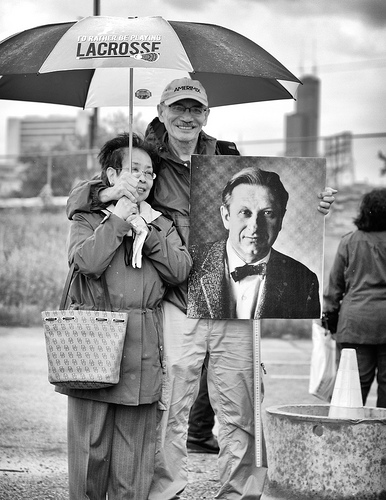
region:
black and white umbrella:
[9, 10, 290, 129]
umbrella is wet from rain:
[23, 15, 284, 125]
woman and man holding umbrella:
[72, 37, 229, 236]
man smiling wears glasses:
[154, 79, 238, 158]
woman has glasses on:
[78, 132, 175, 222]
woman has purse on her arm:
[51, 130, 210, 390]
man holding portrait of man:
[142, 91, 307, 325]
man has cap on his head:
[141, 81, 259, 160]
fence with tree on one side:
[3, 142, 92, 216]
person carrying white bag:
[299, 195, 384, 382]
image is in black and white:
[28, 285, 288, 429]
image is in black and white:
[50, 357, 293, 478]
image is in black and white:
[79, 400, 310, 497]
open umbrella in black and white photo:
[6, 18, 298, 114]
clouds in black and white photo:
[284, 12, 374, 62]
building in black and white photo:
[11, 114, 84, 166]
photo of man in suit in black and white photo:
[191, 136, 332, 338]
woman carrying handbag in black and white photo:
[34, 303, 133, 402]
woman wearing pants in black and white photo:
[62, 393, 156, 495]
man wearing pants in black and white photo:
[163, 283, 267, 482]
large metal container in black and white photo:
[261, 387, 375, 497]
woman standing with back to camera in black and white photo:
[337, 181, 383, 341]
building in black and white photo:
[301, 54, 380, 193]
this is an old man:
[147, 88, 207, 143]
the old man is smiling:
[173, 123, 196, 130]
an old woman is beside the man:
[93, 147, 151, 250]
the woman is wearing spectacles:
[135, 169, 157, 178]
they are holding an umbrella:
[115, 154, 137, 219]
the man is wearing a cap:
[166, 79, 199, 100]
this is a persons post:
[195, 161, 323, 305]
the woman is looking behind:
[339, 238, 379, 332]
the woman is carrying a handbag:
[40, 289, 136, 387]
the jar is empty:
[264, 408, 382, 466]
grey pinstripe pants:
[68, 397, 177, 490]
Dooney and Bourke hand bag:
[17, 293, 133, 413]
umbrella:
[19, 16, 215, 108]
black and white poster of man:
[190, 157, 337, 346]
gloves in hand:
[122, 218, 158, 288]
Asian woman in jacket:
[56, 119, 172, 316]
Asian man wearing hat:
[148, 66, 239, 487]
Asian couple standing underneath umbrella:
[18, 22, 217, 495]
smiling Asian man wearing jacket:
[159, 69, 204, 218]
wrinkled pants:
[170, 316, 263, 495]